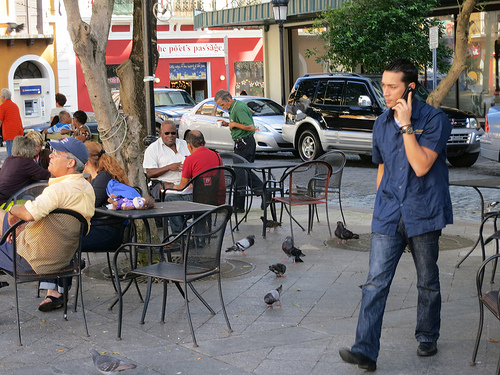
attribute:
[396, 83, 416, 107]
phone — cell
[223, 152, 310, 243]
table — black, metal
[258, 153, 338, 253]
chair — metal, black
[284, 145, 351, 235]
chair — black, metal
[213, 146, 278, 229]
chair — metal, black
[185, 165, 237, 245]
chair — metal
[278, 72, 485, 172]
car — parked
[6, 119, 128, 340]
person — sitting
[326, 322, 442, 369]
shoes — black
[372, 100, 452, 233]
shirt — blue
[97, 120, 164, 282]
trunk — thick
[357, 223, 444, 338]
jeans — blue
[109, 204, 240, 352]
chair — black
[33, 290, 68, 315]
flip flop — black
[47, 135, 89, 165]
cap — blue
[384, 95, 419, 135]
wrist — someone's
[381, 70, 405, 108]
face — man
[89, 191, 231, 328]
table — metal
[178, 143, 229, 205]
shirt — red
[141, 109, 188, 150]
sunglasses — black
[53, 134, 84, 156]
cap —  baseball cap, blue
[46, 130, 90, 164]
cap — blue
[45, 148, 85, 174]
head — man's head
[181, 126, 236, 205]
man — balding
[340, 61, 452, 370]
man — young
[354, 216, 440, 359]
jeans — blue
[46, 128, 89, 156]
cap — blue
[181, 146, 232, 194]
shirt — red